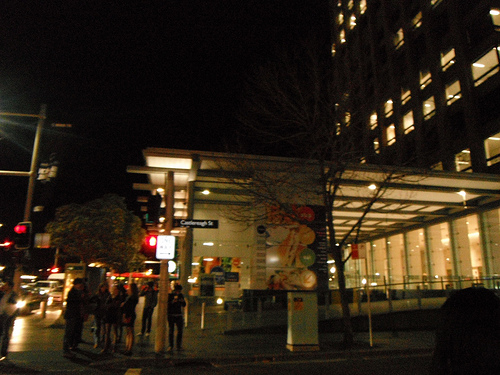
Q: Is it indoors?
A: Yes, it is indoors.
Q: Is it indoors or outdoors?
A: It is indoors.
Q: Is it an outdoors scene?
A: No, it is indoors.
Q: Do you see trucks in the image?
A: No, there are no trucks.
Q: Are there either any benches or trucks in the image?
A: No, there are no trucks or benches.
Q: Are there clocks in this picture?
A: No, there are no clocks.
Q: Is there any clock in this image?
A: No, there are no clocks.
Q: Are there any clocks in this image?
A: No, there are no clocks.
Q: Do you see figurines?
A: No, there are no figurines.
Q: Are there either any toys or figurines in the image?
A: No, there are no figurines or toys.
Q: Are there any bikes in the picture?
A: No, there are no bikes.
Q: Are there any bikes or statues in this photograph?
A: No, there are no bikes or statues.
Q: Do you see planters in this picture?
A: No, there are no planters.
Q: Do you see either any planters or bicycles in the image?
A: No, there are no planters or bicycles.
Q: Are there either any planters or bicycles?
A: No, there are no planters or bicycles.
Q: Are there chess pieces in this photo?
A: No, there are no chess pieces.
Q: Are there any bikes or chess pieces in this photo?
A: No, there are no chess pieces or bikes.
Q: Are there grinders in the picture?
A: No, there are no grinders.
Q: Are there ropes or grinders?
A: No, there are no grinders or ropes.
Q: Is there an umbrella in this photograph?
A: No, there are no umbrellas.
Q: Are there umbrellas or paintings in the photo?
A: No, there are no umbrellas or paintings.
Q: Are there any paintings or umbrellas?
A: No, there are no umbrellas or paintings.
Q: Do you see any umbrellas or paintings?
A: No, there are no umbrellas or paintings.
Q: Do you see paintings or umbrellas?
A: No, there are no umbrellas or paintings.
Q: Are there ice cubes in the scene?
A: No, there are no ice cubes.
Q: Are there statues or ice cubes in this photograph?
A: No, there are no ice cubes or statues.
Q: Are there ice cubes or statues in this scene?
A: No, there are no ice cubes or statues.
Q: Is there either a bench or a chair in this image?
A: No, there are no chairs or benches.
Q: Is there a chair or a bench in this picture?
A: No, there are no chairs or benches.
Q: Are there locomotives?
A: No, there are no locomotives.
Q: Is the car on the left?
A: Yes, the car is on the left of the image.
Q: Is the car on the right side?
A: No, the car is on the left of the image.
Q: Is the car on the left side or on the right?
A: The car is on the left of the image.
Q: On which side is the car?
A: The car is on the left of the image.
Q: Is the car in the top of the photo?
A: No, the car is in the bottom of the image.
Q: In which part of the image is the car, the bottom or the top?
A: The car is in the bottom of the image.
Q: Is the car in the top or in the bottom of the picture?
A: The car is in the bottom of the image.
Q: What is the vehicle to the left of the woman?
A: The vehicle is a car.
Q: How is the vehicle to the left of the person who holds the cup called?
A: The vehicle is a car.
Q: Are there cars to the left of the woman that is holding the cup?
A: Yes, there is a car to the left of the woman.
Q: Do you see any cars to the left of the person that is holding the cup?
A: Yes, there is a car to the left of the woman.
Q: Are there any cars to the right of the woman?
A: No, the car is to the left of the woman.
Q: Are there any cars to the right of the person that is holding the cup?
A: No, the car is to the left of the woman.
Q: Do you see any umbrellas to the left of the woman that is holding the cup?
A: No, there is a car to the left of the woman.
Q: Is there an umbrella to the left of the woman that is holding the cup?
A: No, there is a car to the left of the woman.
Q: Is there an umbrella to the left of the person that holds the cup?
A: No, there is a car to the left of the woman.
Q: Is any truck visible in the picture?
A: No, there are no trucks.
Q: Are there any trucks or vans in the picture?
A: No, there are no trucks or vans.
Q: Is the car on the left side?
A: Yes, the car is on the left of the image.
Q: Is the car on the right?
A: No, the car is on the left of the image.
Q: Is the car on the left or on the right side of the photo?
A: The car is on the left of the image.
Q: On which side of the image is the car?
A: The car is on the left of the image.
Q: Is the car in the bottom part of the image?
A: Yes, the car is in the bottom of the image.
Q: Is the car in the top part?
A: No, the car is in the bottom of the image.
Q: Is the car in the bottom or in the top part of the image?
A: The car is in the bottom of the image.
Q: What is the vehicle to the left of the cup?
A: The vehicle is a car.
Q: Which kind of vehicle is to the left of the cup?
A: The vehicle is a car.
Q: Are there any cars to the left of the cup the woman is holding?
A: Yes, there is a car to the left of the cup.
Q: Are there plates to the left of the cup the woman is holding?
A: No, there is a car to the left of the cup.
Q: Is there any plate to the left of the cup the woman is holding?
A: No, there is a car to the left of the cup.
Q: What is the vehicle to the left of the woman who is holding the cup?
A: The vehicle is a car.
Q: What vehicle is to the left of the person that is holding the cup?
A: The vehicle is a car.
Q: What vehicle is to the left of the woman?
A: The vehicle is a car.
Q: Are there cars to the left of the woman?
A: Yes, there is a car to the left of the woman.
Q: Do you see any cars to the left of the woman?
A: Yes, there is a car to the left of the woman.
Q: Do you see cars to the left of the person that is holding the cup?
A: Yes, there is a car to the left of the woman.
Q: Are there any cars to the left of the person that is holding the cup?
A: Yes, there is a car to the left of the woman.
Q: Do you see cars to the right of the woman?
A: No, the car is to the left of the woman.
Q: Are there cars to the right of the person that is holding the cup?
A: No, the car is to the left of the woman.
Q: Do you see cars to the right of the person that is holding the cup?
A: No, the car is to the left of the woman.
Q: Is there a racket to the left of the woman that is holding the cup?
A: No, there is a car to the left of the woman.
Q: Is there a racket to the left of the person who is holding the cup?
A: No, there is a car to the left of the woman.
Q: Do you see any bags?
A: No, there are no bags.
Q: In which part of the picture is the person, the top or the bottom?
A: The person is in the bottom of the image.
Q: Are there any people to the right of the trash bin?
A: Yes, there is a person to the right of the trash bin.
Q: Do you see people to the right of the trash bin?
A: Yes, there is a person to the right of the trash bin.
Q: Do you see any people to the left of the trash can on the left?
A: No, the person is to the right of the trashcan.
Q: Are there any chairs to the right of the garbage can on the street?
A: No, there is a person to the right of the garbage bin.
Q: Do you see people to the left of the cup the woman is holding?
A: Yes, there is a person to the left of the cup.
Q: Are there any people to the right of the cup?
A: No, the person is to the left of the cup.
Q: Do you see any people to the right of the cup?
A: No, the person is to the left of the cup.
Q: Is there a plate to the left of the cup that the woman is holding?
A: No, there is a person to the left of the cup.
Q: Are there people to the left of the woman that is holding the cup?
A: Yes, there is a person to the left of the woman.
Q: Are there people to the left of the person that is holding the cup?
A: Yes, there is a person to the left of the woman.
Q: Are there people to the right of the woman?
A: No, the person is to the left of the woman.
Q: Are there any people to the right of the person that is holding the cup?
A: No, the person is to the left of the woman.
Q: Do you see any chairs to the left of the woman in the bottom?
A: No, there is a person to the left of the woman.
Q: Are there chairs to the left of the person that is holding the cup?
A: No, there is a person to the left of the woman.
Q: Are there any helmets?
A: No, there are no helmets.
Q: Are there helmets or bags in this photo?
A: No, there are no helmets or bags.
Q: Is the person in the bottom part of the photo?
A: Yes, the person is in the bottom of the image.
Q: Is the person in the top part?
A: No, the person is in the bottom of the image.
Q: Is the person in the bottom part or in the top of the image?
A: The person is in the bottom of the image.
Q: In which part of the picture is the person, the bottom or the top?
A: The person is in the bottom of the image.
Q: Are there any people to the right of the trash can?
A: Yes, there is a person to the right of the trash can.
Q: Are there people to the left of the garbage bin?
A: No, the person is to the right of the garbage bin.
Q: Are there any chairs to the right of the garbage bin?
A: No, there is a person to the right of the garbage bin.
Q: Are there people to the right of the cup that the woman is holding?
A: No, the person is to the left of the cup.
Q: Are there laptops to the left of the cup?
A: No, there is a person to the left of the cup.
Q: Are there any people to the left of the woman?
A: Yes, there is a person to the left of the woman.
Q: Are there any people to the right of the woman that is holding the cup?
A: No, the person is to the left of the woman.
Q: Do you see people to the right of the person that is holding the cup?
A: No, the person is to the left of the woman.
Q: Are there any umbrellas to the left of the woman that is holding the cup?
A: No, there is a person to the left of the woman.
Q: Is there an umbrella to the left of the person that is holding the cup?
A: No, there is a person to the left of the woman.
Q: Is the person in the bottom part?
A: Yes, the person is in the bottom of the image.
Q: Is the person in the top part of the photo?
A: No, the person is in the bottom of the image.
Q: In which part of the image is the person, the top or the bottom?
A: The person is in the bottom of the image.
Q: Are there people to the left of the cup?
A: Yes, there is a person to the left of the cup.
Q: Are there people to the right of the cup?
A: No, the person is to the left of the cup.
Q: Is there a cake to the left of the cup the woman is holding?
A: No, there is a person to the left of the cup.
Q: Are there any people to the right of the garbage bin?
A: Yes, there is a person to the right of the garbage bin.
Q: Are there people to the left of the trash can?
A: No, the person is to the right of the trash can.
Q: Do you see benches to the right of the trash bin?
A: No, there is a person to the right of the trash bin.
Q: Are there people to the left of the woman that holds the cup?
A: Yes, there is a person to the left of the woman.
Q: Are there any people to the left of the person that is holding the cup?
A: Yes, there is a person to the left of the woman.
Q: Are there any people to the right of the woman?
A: No, the person is to the left of the woman.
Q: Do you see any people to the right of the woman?
A: No, the person is to the left of the woman.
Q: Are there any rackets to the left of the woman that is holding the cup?
A: No, there is a person to the left of the woman.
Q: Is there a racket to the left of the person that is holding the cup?
A: No, there is a person to the left of the woman.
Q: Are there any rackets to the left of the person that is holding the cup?
A: No, there is a person to the left of the woman.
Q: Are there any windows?
A: Yes, there is a window.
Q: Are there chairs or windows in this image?
A: Yes, there is a window.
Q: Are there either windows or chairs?
A: Yes, there is a window.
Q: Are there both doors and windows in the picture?
A: No, there is a window but no doors.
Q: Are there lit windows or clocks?
A: Yes, there is a lit window.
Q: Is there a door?
A: No, there are no doors.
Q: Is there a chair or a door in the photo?
A: No, there are no doors or chairs.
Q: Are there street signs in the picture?
A: Yes, there is a street sign.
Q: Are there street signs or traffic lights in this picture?
A: Yes, there is a street sign.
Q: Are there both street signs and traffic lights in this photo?
A: Yes, there are both a street sign and a traffic light.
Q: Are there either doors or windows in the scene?
A: Yes, there is a window.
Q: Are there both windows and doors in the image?
A: No, there is a window but no doors.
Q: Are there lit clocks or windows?
A: Yes, there is a lit window.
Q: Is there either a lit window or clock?
A: Yes, there is a lit window.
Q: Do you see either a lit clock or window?
A: Yes, there is a lit window.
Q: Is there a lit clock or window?
A: Yes, there is a lit window.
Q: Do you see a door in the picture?
A: No, there are no doors.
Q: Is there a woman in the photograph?
A: Yes, there is a woman.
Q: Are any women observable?
A: Yes, there is a woman.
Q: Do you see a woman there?
A: Yes, there is a woman.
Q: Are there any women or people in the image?
A: Yes, there is a woman.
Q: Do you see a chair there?
A: No, there are no chairs.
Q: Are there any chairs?
A: No, there are no chairs.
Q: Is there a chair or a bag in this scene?
A: No, there are no chairs or bags.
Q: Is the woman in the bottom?
A: Yes, the woman is in the bottom of the image.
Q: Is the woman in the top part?
A: No, the woman is in the bottom of the image.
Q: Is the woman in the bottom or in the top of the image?
A: The woman is in the bottom of the image.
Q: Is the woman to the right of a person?
A: Yes, the woman is to the right of a person.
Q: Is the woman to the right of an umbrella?
A: No, the woman is to the right of a person.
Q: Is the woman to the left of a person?
A: No, the woman is to the right of a person.